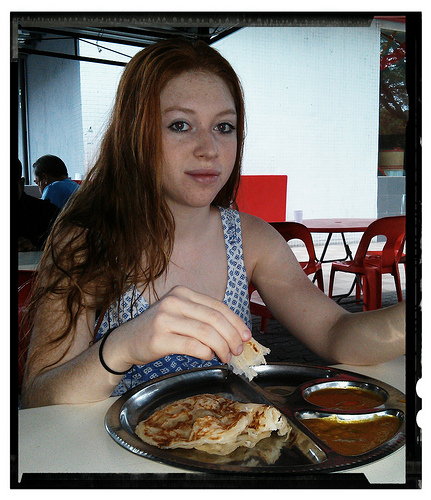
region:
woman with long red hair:
[31, 41, 296, 300]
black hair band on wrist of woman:
[86, 313, 148, 381]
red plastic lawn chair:
[317, 198, 409, 307]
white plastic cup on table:
[287, 207, 307, 226]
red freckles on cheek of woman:
[161, 138, 193, 167]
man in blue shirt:
[25, 155, 89, 209]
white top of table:
[38, 408, 102, 470]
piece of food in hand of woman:
[210, 322, 286, 382]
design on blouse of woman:
[228, 289, 248, 306]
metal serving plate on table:
[96, 354, 407, 476]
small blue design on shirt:
[234, 225, 242, 234]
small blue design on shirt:
[232, 252, 240, 261]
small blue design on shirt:
[234, 261, 240, 273]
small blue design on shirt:
[227, 268, 235, 275]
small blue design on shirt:
[241, 281, 248, 292]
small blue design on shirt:
[229, 297, 237, 305]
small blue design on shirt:
[157, 364, 170, 376]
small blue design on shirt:
[167, 359, 178, 369]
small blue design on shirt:
[130, 369, 143, 381]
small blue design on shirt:
[120, 309, 128, 321]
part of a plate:
[133, 422, 155, 434]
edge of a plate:
[120, 408, 147, 441]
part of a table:
[76, 413, 80, 429]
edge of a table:
[94, 448, 121, 463]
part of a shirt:
[134, 330, 140, 341]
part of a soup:
[303, 417, 322, 439]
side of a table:
[61, 408, 82, 429]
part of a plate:
[247, 443, 259, 459]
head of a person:
[105, 38, 268, 211]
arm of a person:
[34, 299, 211, 410]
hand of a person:
[126, 272, 271, 380]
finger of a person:
[142, 260, 256, 373]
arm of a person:
[257, 257, 375, 365]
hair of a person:
[44, 144, 162, 285]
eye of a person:
[153, 109, 201, 139]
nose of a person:
[180, 137, 224, 172]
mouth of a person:
[172, 164, 228, 198]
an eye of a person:
[214, 114, 250, 134]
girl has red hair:
[91, 62, 278, 312]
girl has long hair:
[48, 36, 270, 301]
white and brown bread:
[129, 375, 271, 455]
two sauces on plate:
[271, 393, 395, 461]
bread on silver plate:
[121, 378, 383, 464]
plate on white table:
[103, 391, 373, 463]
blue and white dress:
[106, 212, 249, 392]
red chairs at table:
[244, 224, 421, 322]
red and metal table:
[273, 187, 382, 283]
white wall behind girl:
[274, 88, 365, 187]